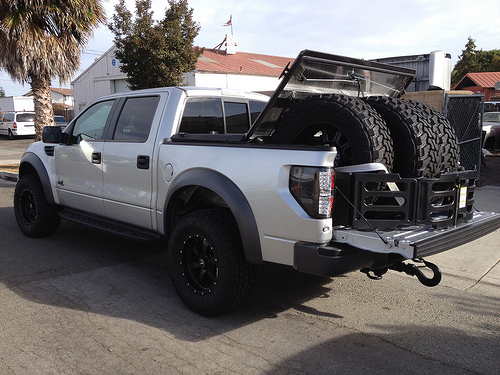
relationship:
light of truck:
[299, 174, 322, 192] [19, 35, 399, 285]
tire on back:
[286, 99, 441, 225] [230, 111, 462, 284]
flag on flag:
[215, 9, 245, 45] [221, 19, 232, 27]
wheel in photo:
[316, 110, 438, 193] [19, 35, 399, 285]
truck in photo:
[19, 35, 399, 285] [3, 0, 470, 368]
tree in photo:
[5, 13, 93, 149] [3, 0, 470, 368]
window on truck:
[190, 95, 255, 131] [9, 51, 496, 320]